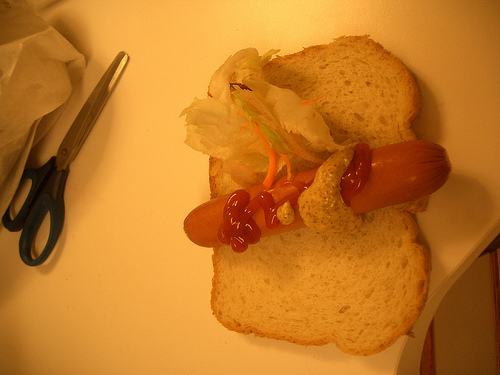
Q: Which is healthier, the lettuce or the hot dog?
A: The lettuce is healthier than the hot dog.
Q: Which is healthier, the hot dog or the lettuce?
A: The lettuce is healthier than the hot dog.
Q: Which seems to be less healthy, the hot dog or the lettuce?
A: The hot dog is less healthy than the lettuce.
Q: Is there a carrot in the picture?
A: Yes, there is a carrot.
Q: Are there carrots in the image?
A: Yes, there is a carrot.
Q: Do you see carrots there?
A: Yes, there is a carrot.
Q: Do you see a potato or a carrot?
A: Yes, there is a carrot.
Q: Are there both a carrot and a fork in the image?
A: No, there is a carrot but no forks.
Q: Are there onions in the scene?
A: No, there are no onions.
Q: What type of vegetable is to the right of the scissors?
A: The vegetable is a carrot.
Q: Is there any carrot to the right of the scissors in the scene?
A: Yes, there is a carrot to the right of the scissors.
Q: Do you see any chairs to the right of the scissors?
A: No, there is a carrot to the right of the scissors.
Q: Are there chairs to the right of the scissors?
A: No, there is a carrot to the right of the scissors.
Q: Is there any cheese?
A: No, there is no cheese.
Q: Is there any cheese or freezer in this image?
A: No, there are no cheese or refrigerators.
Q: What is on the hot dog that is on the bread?
A: The seasonings are on the hot dog.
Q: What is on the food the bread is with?
A: The seasonings are on the hot dog.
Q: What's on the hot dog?
A: The seasonings are on the hot dog.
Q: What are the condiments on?
A: The condiments are on the hot dog.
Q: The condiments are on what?
A: The condiments are on the hot dog.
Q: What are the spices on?
A: The condiments are on the hot dog.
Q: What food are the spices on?
A: The spices are on the hot dog.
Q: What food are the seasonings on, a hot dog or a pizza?
A: The seasonings are on a hot dog.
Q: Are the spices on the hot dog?
A: Yes, the spices are on the hot dog.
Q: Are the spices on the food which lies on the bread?
A: Yes, the spices are on the hot dog.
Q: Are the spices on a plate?
A: No, the spices are on the hot dog.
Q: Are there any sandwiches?
A: Yes, there is a sandwich.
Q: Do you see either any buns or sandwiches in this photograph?
A: Yes, there is a sandwich.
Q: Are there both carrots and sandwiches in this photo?
A: Yes, there are both a sandwich and a carrot.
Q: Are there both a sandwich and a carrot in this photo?
A: Yes, there are both a sandwich and a carrot.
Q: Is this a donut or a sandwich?
A: This is a sandwich.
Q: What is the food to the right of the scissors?
A: The food is a sandwich.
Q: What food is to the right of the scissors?
A: The food is a sandwich.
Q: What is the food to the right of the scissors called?
A: The food is a sandwich.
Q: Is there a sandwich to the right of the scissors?
A: Yes, there is a sandwich to the right of the scissors.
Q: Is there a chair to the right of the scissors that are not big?
A: No, there is a sandwich to the right of the scissors.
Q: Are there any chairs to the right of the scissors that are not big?
A: No, there is a sandwich to the right of the scissors.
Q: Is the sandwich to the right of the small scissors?
A: Yes, the sandwich is to the right of the scissors.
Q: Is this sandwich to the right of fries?
A: No, the sandwich is to the right of the scissors.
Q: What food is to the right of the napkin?
A: The food is a sandwich.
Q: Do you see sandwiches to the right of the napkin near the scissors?
A: Yes, there is a sandwich to the right of the napkin.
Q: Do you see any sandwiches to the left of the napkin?
A: No, the sandwich is to the right of the napkin.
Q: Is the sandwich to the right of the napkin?
A: Yes, the sandwich is to the right of the napkin.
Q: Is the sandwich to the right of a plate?
A: No, the sandwich is to the right of the napkin.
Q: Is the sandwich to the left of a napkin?
A: No, the sandwich is to the right of a napkin.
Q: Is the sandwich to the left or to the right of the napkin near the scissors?
A: The sandwich is to the right of the napkin.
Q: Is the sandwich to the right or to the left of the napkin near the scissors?
A: The sandwich is to the right of the napkin.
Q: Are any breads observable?
A: Yes, there is a bread.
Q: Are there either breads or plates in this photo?
A: Yes, there is a bread.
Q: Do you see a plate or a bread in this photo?
A: Yes, there is a bread.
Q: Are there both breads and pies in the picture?
A: No, there is a bread but no pies.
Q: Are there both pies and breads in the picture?
A: No, there is a bread but no pies.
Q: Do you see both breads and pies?
A: No, there is a bread but no pies.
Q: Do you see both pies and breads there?
A: No, there is a bread but no pies.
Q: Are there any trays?
A: No, there are no trays.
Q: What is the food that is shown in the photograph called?
A: The food is a bread.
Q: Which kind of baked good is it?
A: The food is a bread.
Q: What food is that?
A: This is a bread.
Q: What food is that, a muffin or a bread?
A: This is a bread.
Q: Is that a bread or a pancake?
A: That is a bread.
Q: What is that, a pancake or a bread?
A: That is a bread.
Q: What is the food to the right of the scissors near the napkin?
A: The food is a bread.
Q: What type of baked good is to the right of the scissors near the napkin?
A: The food is a bread.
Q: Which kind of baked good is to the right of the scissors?
A: The food is a bread.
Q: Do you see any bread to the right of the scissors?
A: Yes, there is a bread to the right of the scissors.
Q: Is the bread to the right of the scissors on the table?
A: Yes, the bread is to the right of the scissors.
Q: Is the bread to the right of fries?
A: No, the bread is to the right of the scissors.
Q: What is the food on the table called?
A: The food is a bread.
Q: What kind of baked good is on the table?
A: The food is a bread.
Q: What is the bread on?
A: The bread is on the table.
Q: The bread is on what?
A: The bread is on the table.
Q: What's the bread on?
A: The bread is on the table.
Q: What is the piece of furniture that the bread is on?
A: The piece of furniture is a table.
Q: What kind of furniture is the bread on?
A: The bread is on the table.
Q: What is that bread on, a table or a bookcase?
A: The bread is on a table.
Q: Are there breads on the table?
A: Yes, there is a bread on the table.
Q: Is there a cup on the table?
A: No, there is a bread on the table.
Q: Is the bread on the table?
A: Yes, the bread is on the table.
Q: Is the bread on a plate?
A: No, the bread is on the table.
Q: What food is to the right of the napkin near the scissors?
A: The food is a bread.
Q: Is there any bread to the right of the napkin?
A: Yes, there is a bread to the right of the napkin.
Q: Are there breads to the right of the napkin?
A: Yes, there is a bread to the right of the napkin.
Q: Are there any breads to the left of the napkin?
A: No, the bread is to the right of the napkin.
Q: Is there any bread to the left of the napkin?
A: No, the bread is to the right of the napkin.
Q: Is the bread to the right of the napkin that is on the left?
A: Yes, the bread is to the right of the napkin.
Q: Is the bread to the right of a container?
A: No, the bread is to the right of the napkin.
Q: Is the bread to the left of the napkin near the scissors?
A: No, the bread is to the right of the napkin.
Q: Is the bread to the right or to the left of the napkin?
A: The bread is to the right of the napkin.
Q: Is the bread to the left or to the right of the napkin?
A: The bread is to the right of the napkin.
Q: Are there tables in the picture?
A: Yes, there is a table.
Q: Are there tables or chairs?
A: Yes, there is a table.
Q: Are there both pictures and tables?
A: No, there is a table but no pictures.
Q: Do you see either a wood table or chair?
A: Yes, there is a wood table.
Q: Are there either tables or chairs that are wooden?
A: Yes, the table is wooden.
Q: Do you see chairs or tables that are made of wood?
A: Yes, the table is made of wood.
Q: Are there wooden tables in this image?
A: Yes, there is a wood table.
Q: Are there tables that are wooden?
A: Yes, there is a table that is wooden.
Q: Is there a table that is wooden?
A: Yes, there is a table that is wooden.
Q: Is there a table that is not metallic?
A: Yes, there is a wooden table.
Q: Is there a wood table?
A: Yes, there is a table that is made of wood.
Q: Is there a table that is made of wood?
A: Yes, there is a table that is made of wood.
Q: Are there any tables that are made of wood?
A: Yes, there is a table that is made of wood.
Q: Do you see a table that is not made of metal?
A: Yes, there is a table that is made of wood.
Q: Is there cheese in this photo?
A: No, there is no cheese.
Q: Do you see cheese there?
A: No, there is no cheese.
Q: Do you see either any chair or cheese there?
A: No, there are no cheese or chairs.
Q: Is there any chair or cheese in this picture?
A: No, there are no cheese or chairs.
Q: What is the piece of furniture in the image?
A: The piece of furniture is a table.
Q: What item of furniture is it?
A: The piece of furniture is a table.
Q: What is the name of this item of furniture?
A: This is a table.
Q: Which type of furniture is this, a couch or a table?
A: This is a table.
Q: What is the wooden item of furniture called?
A: The piece of furniture is a table.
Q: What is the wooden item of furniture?
A: The piece of furniture is a table.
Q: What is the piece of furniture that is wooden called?
A: The piece of furniture is a table.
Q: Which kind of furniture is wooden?
A: The furniture is a table.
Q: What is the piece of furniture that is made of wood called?
A: The piece of furniture is a table.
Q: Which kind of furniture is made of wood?
A: The furniture is a table.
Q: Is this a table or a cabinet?
A: This is a table.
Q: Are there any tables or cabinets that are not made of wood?
A: No, there is a table but it is made of wood.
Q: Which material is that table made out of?
A: The table is made of wood.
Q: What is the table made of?
A: The table is made of wood.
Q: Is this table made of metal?
A: No, the table is made of wood.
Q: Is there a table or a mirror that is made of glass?
A: No, there is a table but it is made of wood.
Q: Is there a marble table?
A: No, there is a table but it is made of wood.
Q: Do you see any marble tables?
A: No, there is a table but it is made of wood.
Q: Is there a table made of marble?
A: No, there is a table but it is made of wood.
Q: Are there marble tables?
A: No, there is a table but it is made of wood.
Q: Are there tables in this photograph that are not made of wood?
A: No, there is a table but it is made of wood.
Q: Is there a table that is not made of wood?
A: No, there is a table but it is made of wood.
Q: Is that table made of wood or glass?
A: The table is made of wood.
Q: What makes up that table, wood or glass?
A: The table is made of wood.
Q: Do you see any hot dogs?
A: Yes, there is a hot dog.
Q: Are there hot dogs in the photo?
A: Yes, there is a hot dog.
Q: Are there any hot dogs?
A: Yes, there is a hot dog.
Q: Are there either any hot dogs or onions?
A: Yes, there is a hot dog.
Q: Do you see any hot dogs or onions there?
A: Yes, there is a hot dog.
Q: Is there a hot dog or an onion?
A: Yes, there is a hot dog.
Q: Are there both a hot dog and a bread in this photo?
A: Yes, there are both a hot dog and a bread.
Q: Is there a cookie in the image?
A: No, there are no cookies.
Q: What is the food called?
A: The food is a hot dog.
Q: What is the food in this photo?
A: The food is a hot dog.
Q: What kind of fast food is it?
A: The food is a hot dog.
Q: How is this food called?
A: That is a hot dog.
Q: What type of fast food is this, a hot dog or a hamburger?
A: That is a hot dog.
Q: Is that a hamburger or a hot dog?
A: That is a hot dog.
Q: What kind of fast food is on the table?
A: The food is a hot dog.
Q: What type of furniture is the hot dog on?
A: The hot dog is on the table.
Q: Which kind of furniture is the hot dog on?
A: The hot dog is on the table.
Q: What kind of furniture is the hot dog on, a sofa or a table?
A: The hot dog is on a table.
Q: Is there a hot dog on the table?
A: Yes, there is a hot dog on the table.